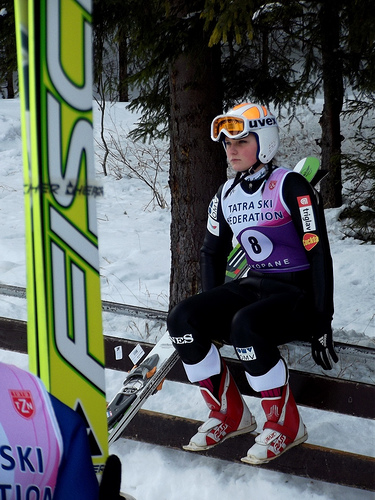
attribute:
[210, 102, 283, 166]
helmet — white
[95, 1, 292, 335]
tree — brown, thick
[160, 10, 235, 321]
trunk — thick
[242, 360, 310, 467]
shoes — red, white, for skiing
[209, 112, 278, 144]
goggles — orange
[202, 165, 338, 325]
top — multicolor, mutlicolored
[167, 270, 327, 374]
pants — black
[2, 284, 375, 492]
ledge — brown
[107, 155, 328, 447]
skis — white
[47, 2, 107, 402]
words — white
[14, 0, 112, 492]
gear — in the foreground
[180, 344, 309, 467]
boots — red, white